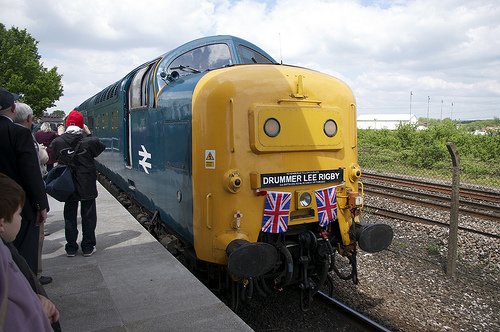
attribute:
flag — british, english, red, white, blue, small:
[261, 188, 291, 233]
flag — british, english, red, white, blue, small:
[314, 187, 338, 226]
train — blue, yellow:
[68, 33, 393, 314]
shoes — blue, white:
[64, 245, 98, 257]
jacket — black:
[49, 126, 106, 200]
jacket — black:
[0, 116, 50, 220]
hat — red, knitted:
[66, 110, 85, 128]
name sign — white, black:
[260, 169, 343, 189]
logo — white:
[137, 144, 152, 174]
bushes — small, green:
[357, 123, 499, 188]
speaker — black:
[224, 238, 278, 277]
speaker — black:
[348, 221, 394, 253]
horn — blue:
[159, 71, 179, 80]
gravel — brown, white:
[234, 168, 499, 331]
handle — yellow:
[276, 99, 323, 107]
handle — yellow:
[227, 97, 236, 154]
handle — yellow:
[205, 192, 211, 229]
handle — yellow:
[349, 103, 357, 149]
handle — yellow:
[356, 180, 365, 210]